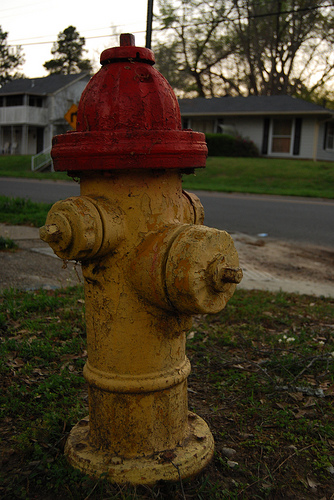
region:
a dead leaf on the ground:
[223, 445, 237, 459]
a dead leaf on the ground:
[292, 406, 307, 419]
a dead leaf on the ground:
[303, 467, 316, 489]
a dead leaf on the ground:
[273, 396, 288, 409]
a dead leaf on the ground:
[234, 360, 248, 369]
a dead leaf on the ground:
[255, 353, 268, 365]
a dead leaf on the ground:
[302, 373, 313, 386]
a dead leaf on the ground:
[8, 356, 21, 367]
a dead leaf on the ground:
[21, 325, 28, 331]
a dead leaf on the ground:
[56, 360, 69, 371]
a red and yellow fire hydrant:
[51, 25, 233, 469]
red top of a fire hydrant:
[26, 7, 217, 179]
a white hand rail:
[26, 137, 56, 177]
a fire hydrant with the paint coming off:
[46, 192, 253, 339]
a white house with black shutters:
[168, 84, 314, 163]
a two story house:
[0, 67, 81, 160]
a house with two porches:
[0, 62, 86, 155]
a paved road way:
[176, 177, 315, 238]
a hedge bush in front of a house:
[193, 124, 282, 173]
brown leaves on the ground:
[8, 294, 72, 379]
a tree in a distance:
[47, 25, 84, 72]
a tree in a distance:
[307, 16, 328, 92]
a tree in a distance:
[232, 14, 253, 87]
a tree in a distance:
[159, 32, 215, 102]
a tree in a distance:
[0, 29, 22, 86]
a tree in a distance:
[10, 42, 31, 80]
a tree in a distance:
[146, 31, 188, 101]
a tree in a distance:
[222, 6, 265, 93]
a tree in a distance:
[289, 12, 329, 86]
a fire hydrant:
[41, 7, 266, 486]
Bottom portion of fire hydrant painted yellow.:
[36, 173, 250, 496]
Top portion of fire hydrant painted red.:
[44, 24, 221, 183]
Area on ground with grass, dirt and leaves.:
[214, 318, 318, 476]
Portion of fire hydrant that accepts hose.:
[142, 220, 256, 334]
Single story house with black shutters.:
[141, 89, 323, 159]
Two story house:
[0, 60, 88, 159]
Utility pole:
[138, 0, 161, 58]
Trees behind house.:
[152, 6, 327, 137]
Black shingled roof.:
[169, 86, 333, 124]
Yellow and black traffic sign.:
[62, 102, 82, 132]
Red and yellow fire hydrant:
[53, 36, 236, 341]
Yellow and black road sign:
[57, 95, 83, 133]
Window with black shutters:
[254, 117, 307, 168]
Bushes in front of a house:
[215, 133, 264, 164]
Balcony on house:
[0, 86, 44, 134]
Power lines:
[155, 5, 300, 27]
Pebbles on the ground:
[216, 427, 251, 478]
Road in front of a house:
[210, 183, 309, 233]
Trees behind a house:
[167, 31, 307, 104]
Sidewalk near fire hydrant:
[5, 233, 70, 299]